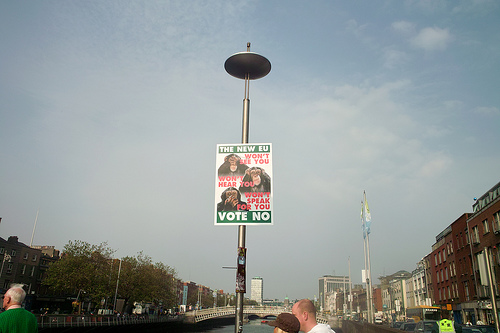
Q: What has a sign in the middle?
A: A city scene.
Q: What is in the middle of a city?
A: A sign.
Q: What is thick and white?
A: The clouds.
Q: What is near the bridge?
A: The trees.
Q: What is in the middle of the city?
A: A sign.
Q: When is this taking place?
A: Daytime.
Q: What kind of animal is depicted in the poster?
A: Chimpanzee.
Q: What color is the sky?
A: Blue and white.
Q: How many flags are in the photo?
A: One.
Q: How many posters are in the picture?
A: One.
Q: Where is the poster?
A: On a metal pole.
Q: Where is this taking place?
A: On a street corner.